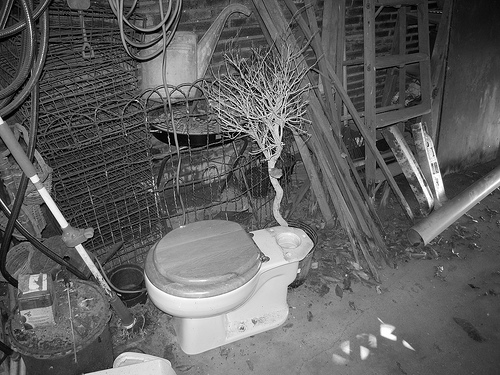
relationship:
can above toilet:
[131, 3, 250, 97] [139, 215, 316, 355]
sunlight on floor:
[324, 315, 416, 365] [313, 306, 433, 366]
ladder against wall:
[319, 0, 438, 182] [0, 2, 495, 283]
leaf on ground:
[335, 285, 343, 298] [22, 170, 498, 372]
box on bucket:
[14, 266, 58, 336] [1, 272, 112, 373]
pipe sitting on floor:
[406, 166, 500, 249] [2, 162, 497, 373]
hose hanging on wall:
[0, 2, 52, 280] [0, 2, 495, 283]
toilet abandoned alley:
[139, 215, 316, 355] [4, 12, 484, 362]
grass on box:
[218, 94, 294, 173] [16, 269, 57, 331]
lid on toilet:
[152, 216, 261, 288] [139, 215, 316, 355]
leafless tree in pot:
[198, 24, 308, 230] [271, 229, 319, 288]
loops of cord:
[84, 103, 173, 181] [109, 0, 193, 61]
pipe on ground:
[400, 164, 497, 250] [22, 170, 498, 372]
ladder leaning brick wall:
[319, 0, 439, 193] [2, 1, 497, 278]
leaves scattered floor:
[329, 242, 491, 359] [34, 202, 480, 357]